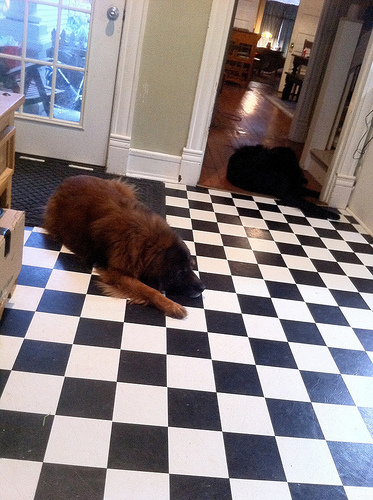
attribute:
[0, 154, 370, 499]
floor — checkered, black, white, tile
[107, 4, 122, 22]
knob — silver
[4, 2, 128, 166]
door — framed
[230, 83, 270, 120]
reflection — distant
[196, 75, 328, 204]
floor — hard wood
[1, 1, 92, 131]
panes — glass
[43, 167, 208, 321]
dog — brown, beautiful, laying, sleeping, black, furry, lying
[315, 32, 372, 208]
trim — white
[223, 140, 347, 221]
dog — large, furry, black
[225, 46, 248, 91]
chair — brown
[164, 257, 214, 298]
face — black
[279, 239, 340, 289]
tiles — black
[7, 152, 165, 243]
mat — black